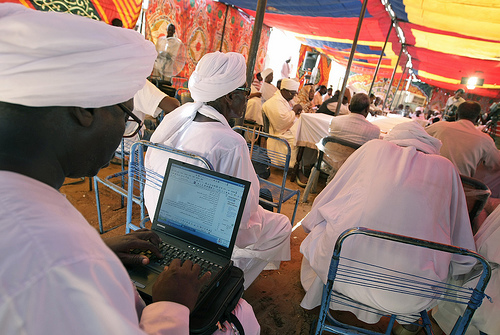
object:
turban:
[188, 50, 251, 103]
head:
[187, 51, 253, 119]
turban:
[0, 5, 160, 109]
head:
[0, 2, 159, 181]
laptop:
[110, 158, 253, 310]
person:
[324, 92, 380, 148]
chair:
[123, 140, 215, 235]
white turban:
[382, 120, 443, 154]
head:
[382, 119, 442, 154]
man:
[1, 1, 264, 334]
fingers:
[156, 256, 213, 283]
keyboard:
[165, 250, 181, 258]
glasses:
[115, 102, 143, 139]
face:
[69, 96, 135, 179]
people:
[263, 79, 300, 170]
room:
[1, 1, 499, 326]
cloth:
[275, 1, 424, 73]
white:
[11, 215, 54, 272]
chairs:
[325, 226, 498, 334]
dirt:
[267, 282, 295, 315]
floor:
[258, 270, 310, 328]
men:
[141, 51, 289, 273]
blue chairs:
[227, 125, 302, 226]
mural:
[143, 2, 248, 50]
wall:
[156, 0, 251, 88]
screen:
[156, 161, 246, 248]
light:
[466, 76, 478, 90]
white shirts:
[329, 114, 378, 141]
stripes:
[229, 7, 497, 76]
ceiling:
[416, 10, 497, 75]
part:
[306, 37, 350, 48]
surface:
[403, 4, 499, 83]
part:
[175, 252, 207, 258]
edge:
[243, 181, 252, 200]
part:
[165, 118, 188, 131]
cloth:
[151, 103, 199, 142]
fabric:
[362, 26, 385, 47]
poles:
[331, 0, 414, 114]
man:
[299, 120, 478, 326]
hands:
[98, 228, 162, 268]